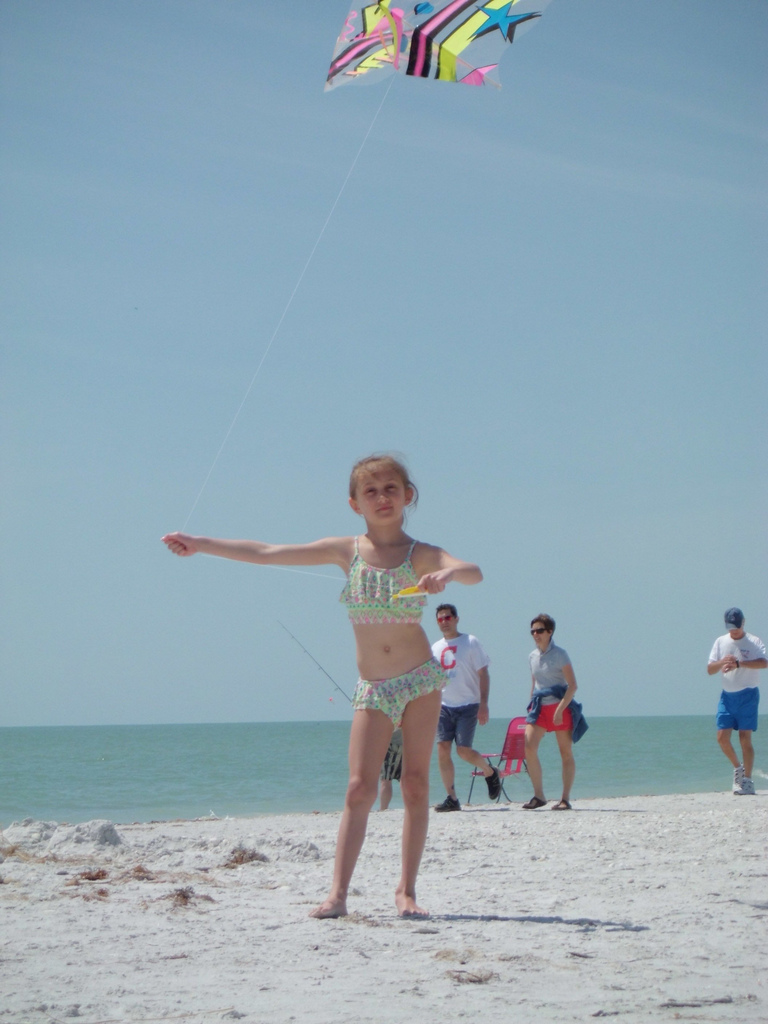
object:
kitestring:
[186, 550, 441, 597]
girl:
[349, 454, 420, 509]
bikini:
[339, 534, 449, 728]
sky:
[0, 0, 767, 728]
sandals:
[522, 796, 572, 812]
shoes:
[434, 766, 501, 813]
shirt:
[430, 633, 491, 709]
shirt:
[708, 632, 766, 693]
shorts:
[715, 687, 759, 733]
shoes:
[733, 764, 755, 794]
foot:
[310, 895, 350, 919]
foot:
[395, 892, 430, 917]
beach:
[0, 788, 767, 1021]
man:
[430, 603, 501, 813]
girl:
[160, 455, 483, 920]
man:
[707, 605, 768, 794]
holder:
[391, 586, 421, 600]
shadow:
[409, 915, 651, 926]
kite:
[323, 0, 540, 91]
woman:
[523, 613, 589, 810]